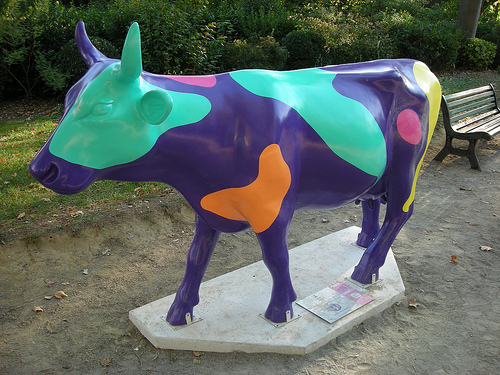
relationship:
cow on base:
[17, 4, 460, 329] [113, 221, 415, 352]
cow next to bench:
[17, 4, 460, 329] [439, 81, 499, 164]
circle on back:
[162, 66, 219, 96] [139, 52, 430, 79]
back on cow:
[139, 52, 430, 79] [17, 4, 460, 329]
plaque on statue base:
[290, 257, 402, 331] [124, 214, 409, 366]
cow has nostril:
[17, 4, 460, 329] [37, 159, 64, 186]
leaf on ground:
[46, 279, 71, 302] [2, 239, 125, 355]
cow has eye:
[17, 4, 460, 329] [77, 97, 117, 124]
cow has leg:
[17, 4, 460, 329] [253, 224, 302, 331]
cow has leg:
[17, 4, 460, 329] [346, 194, 420, 294]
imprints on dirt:
[2, 315, 63, 367] [8, 286, 84, 371]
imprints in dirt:
[12, 264, 90, 307] [6, 248, 126, 360]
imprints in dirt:
[159, 355, 191, 367] [110, 348, 339, 373]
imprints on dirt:
[330, 343, 373, 370] [321, 337, 488, 373]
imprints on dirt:
[377, 318, 418, 350] [348, 305, 495, 372]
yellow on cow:
[422, 67, 440, 97] [17, 4, 460, 329]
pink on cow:
[397, 116, 418, 136] [17, 4, 460, 329]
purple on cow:
[204, 133, 231, 160] [17, 4, 460, 329]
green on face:
[68, 94, 149, 161] [21, 60, 142, 181]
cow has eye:
[17, 4, 460, 329] [87, 97, 117, 122]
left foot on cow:
[164, 302, 198, 325] [28, 14, 448, 321]